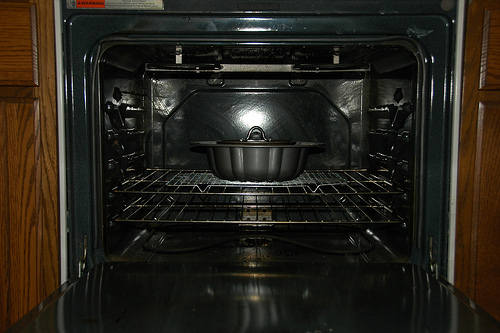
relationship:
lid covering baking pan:
[215, 124, 298, 145] [191, 127, 323, 182]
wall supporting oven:
[198, 92, 327, 119] [158, 70, 413, 310]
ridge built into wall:
[101, 101, 144, 112] [93, 47, 151, 262]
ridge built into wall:
[108, 128, 147, 140] [93, 47, 151, 262]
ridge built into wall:
[108, 149, 147, 169] [93, 47, 151, 262]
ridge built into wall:
[112, 169, 146, 197] [93, 47, 151, 262]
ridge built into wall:
[110, 193, 145, 230] [93, 47, 151, 262]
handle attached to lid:
[240, 124, 274, 143] [213, 123, 299, 146]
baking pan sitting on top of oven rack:
[191, 127, 323, 182] [111, 167, 402, 197]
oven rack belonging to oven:
[111, 167, 402, 197] [62, 3, 467, 291]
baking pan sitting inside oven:
[191, 127, 323, 182] [62, 3, 467, 291]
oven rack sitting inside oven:
[111, 167, 402, 197] [4, 0, 499, 332]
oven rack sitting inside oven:
[112, 195, 399, 224] [4, 0, 499, 332]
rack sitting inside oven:
[164, 165, 348, 193] [4, 0, 499, 332]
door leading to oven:
[77, 236, 482, 318] [100, 73, 440, 230]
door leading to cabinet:
[0, 20, 68, 310] [1, 1, 57, 331]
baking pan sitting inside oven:
[191, 127, 323, 182] [4, 0, 499, 332]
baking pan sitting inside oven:
[191, 127, 323, 182] [89, 31, 426, 331]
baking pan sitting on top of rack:
[191, 127, 323, 182] [145, 175, 397, 215]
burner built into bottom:
[152, 209, 343, 271] [109, 202, 415, 264]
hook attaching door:
[424, 235, 440, 279] [9, 255, 497, 331]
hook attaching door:
[76, 229, 92, 279] [9, 255, 497, 331]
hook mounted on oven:
[197, 47, 309, 70] [4, 0, 499, 332]